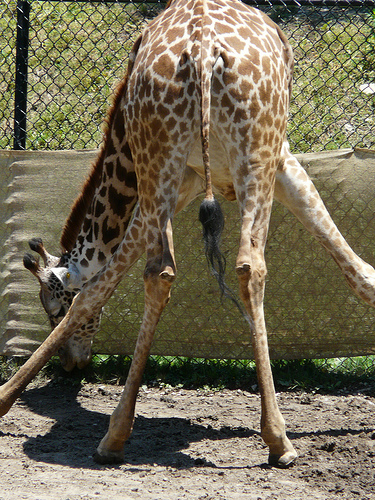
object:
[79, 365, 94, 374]
grass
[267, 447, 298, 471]
feet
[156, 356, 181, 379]
grass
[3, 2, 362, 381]
fence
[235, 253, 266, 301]
knobby knees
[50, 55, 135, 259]
mane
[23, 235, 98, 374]
head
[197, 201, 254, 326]
hair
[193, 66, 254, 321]
tail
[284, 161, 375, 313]
legs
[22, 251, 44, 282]
horns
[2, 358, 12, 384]
grass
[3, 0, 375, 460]
animal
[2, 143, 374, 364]
cloth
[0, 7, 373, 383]
area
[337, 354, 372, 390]
grass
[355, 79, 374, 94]
rocks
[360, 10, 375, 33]
branches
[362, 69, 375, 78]
bush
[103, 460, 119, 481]
sand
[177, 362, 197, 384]
grass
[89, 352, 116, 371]
grass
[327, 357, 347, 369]
object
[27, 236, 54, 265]
horns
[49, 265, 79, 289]
ear